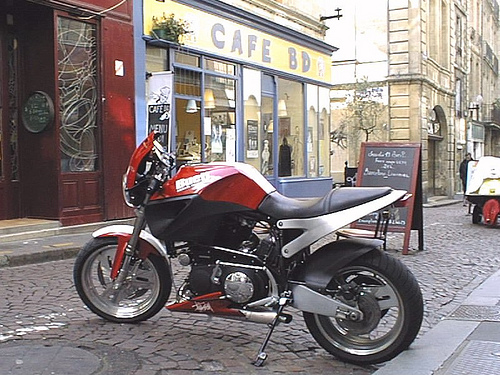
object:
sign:
[141, 0, 331, 81]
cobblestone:
[444, 230, 451, 235]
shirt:
[459, 158, 478, 181]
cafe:
[142, 0, 342, 198]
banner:
[145, 70, 177, 160]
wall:
[140, 0, 332, 83]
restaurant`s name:
[210, 22, 311, 73]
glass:
[282, 94, 288, 130]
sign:
[18, 90, 57, 133]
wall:
[17, 12, 57, 219]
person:
[459, 153, 470, 201]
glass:
[58, 18, 94, 163]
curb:
[371, 269, 500, 374]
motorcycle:
[72, 129, 422, 366]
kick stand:
[251, 291, 292, 366]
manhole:
[0, 338, 104, 375]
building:
[326, 0, 500, 207]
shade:
[183, 97, 199, 116]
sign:
[349, 142, 421, 254]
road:
[0, 197, 498, 373]